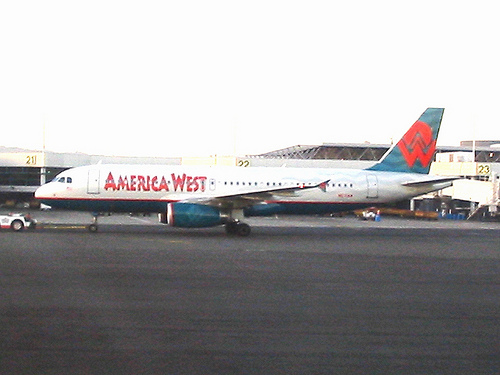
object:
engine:
[167, 202, 229, 227]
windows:
[223, 180, 228, 185]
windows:
[229, 181, 235, 186]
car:
[0, 211, 43, 233]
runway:
[29, 205, 358, 353]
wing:
[177, 177, 342, 207]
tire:
[236, 222, 252, 237]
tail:
[363, 105, 444, 175]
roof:
[237, 137, 499, 167]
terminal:
[4, 136, 496, 231]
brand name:
[103, 171, 207, 192]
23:
[478, 164, 490, 174]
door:
[86, 168, 101, 195]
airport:
[3, 135, 495, 222]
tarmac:
[1, 228, 494, 372]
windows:
[278, 182, 282, 186]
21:
[25, 155, 37, 164]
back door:
[365, 173, 379, 199]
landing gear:
[88, 211, 100, 235]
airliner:
[34, 107, 467, 236]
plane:
[33, 108, 468, 238]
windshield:
[52, 176, 64, 181]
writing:
[101, 166, 205, 194]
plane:
[39, 219, 484, 347]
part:
[172, 198, 186, 221]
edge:
[238, 218, 255, 226]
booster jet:
[166, 201, 229, 228]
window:
[349, 183, 353, 187]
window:
[344, 183, 347, 187]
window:
[337, 183, 341, 187]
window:
[332, 183, 335, 187]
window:
[278, 182, 283, 186]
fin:
[403, 171, 464, 196]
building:
[0, 150, 40, 207]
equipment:
[84, 212, 256, 240]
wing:
[402, 170, 472, 188]